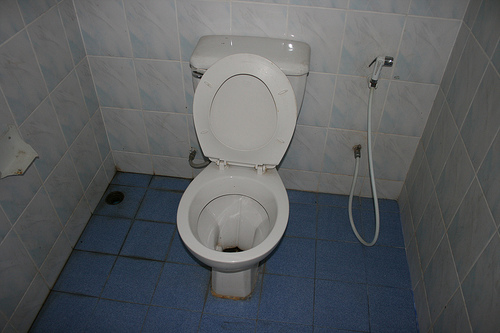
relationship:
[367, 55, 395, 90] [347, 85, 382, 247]
spray gun attached white cord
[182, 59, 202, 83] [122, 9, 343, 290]
flush handle on toilet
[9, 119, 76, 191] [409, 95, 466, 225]
roll holder on wall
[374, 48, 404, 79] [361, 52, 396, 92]
spout of spray gun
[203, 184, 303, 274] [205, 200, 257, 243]
interior of bowl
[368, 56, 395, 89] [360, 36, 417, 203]
faucet handle in wall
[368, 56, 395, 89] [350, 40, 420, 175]
faucet handle in wall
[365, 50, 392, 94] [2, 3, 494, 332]
faucet handle in wall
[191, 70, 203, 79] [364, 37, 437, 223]
flush handle in wall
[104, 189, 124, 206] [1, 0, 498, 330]
brown spot in corner of bathroom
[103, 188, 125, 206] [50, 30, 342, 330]
spot in corner of bathroom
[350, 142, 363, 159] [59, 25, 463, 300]
spot in corner of bathroom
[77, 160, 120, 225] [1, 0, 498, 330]
spot in corner of bathroom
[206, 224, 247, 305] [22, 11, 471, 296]
spot in corner of bathroom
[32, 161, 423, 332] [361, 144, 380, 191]
tile on ground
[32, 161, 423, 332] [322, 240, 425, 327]
tile on floor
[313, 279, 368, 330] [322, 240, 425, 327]
tile on floor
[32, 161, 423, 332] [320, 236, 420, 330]
tile on floor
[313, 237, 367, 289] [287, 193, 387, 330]
blue tile on floor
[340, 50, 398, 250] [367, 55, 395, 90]
hose with spray gun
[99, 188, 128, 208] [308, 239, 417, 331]
drain on floor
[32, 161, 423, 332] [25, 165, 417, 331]
tile on floor